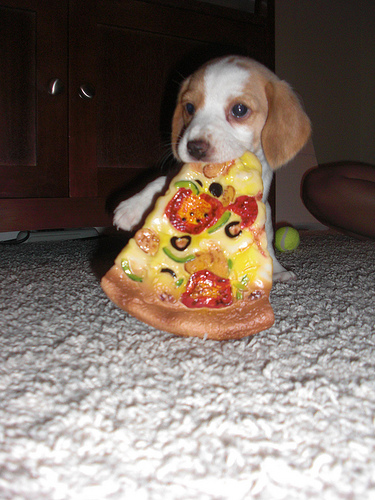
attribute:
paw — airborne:
[111, 164, 183, 233]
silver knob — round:
[50, 60, 100, 116]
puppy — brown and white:
[95, 47, 316, 346]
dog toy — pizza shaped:
[100, 148, 276, 340]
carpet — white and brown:
[1, 225, 372, 499]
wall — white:
[272, 1, 371, 229]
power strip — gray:
[1, 226, 100, 247]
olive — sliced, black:
[167, 230, 197, 255]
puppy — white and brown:
[112, 53, 311, 281]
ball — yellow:
[276, 225, 302, 252]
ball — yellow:
[281, 223, 296, 248]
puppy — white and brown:
[163, 38, 334, 256]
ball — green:
[273, 225, 300, 253]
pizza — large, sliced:
[99, 148, 275, 340]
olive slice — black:
[223, 218, 241, 239]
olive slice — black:
[170, 232, 190, 251]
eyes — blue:
[184, 102, 248, 118]